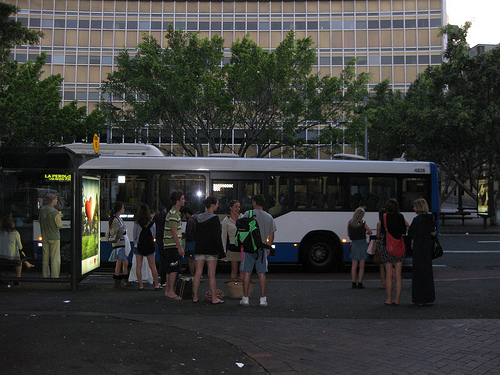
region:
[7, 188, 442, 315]
People standing near a bus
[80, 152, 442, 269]
White and blue transit bus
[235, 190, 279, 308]
Man wearing a black and green backpack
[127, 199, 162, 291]
Woman in shorts wearing a backpack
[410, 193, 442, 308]
Woman in black holding a purse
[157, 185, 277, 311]
People conversing at a bus stop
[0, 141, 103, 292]
Bus stop shelter and bench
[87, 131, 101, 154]
Yellow and black traffic sign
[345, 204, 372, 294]
Woman wearing a black shirt and jean skirt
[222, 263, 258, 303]
Tan and brown purse on the ground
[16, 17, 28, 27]
glass window on building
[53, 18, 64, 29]
glass window on building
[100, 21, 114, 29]
glass window on building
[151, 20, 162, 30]
glass window on building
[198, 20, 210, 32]
glass window on building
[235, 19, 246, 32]
glass window on building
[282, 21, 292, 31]
glass window on building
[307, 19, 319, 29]
glass window on building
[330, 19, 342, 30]
glass window on building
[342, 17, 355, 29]
glass window on building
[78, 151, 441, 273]
a white and blue bus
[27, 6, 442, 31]
a row of windows of a building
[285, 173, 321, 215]
a window of a bus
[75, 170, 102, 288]
a sign that is lit up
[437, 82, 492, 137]
the leaves of a tree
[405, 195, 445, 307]
a woman wearing black holding a black purse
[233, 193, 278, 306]
a man holding a black and green bag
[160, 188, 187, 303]
a man wearing a green, black, and white striped shirt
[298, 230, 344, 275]
the wheel of a bus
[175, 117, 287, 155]
the branches of a tree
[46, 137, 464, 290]
A large blue and white bus.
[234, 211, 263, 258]
the man has a black and green backpack.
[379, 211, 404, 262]
The woman has a large red purse.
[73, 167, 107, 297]
An advertisement at the bus stop.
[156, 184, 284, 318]
a group of people wait for the bus.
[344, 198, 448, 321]
Several women approach the bus.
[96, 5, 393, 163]
There is a large tree above the bus.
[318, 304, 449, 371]
The ground has a cobblestone pattern.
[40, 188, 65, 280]
A man in gray waits for the bus.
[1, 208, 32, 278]
A woman sits on the bench at the bus stop.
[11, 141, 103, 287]
Bus stop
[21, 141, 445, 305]
People standing at a bus stop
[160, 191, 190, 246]
Man wearing a striped shirt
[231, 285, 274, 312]
Write sneakers on the pavement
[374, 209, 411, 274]
Red lady handbag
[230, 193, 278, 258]
man carrying a green and black backpack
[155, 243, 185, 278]
Man wearing black shorts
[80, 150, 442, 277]
Blue and white bus at a bus stop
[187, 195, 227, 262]
A woman wearing a hoodie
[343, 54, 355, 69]
A window on a building.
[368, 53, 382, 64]
A window on a building.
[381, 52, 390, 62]
A window on a building.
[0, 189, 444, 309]
group of people standing by the bus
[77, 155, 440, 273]
left side of the blue and white bus